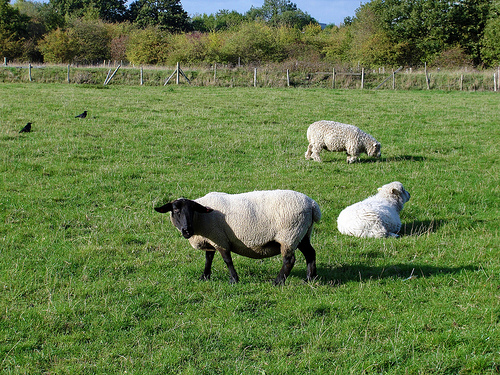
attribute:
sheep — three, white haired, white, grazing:
[171, 102, 421, 271]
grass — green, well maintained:
[4, 81, 488, 260]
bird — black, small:
[9, 119, 32, 147]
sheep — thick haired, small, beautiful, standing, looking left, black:
[184, 194, 322, 268]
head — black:
[164, 194, 199, 242]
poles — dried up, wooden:
[170, 59, 188, 84]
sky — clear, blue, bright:
[299, 1, 359, 20]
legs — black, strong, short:
[193, 258, 243, 290]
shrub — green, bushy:
[226, 24, 294, 64]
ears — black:
[154, 199, 218, 212]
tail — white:
[312, 202, 323, 222]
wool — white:
[254, 223, 279, 233]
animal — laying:
[351, 169, 420, 247]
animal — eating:
[299, 118, 384, 165]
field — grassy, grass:
[41, 59, 491, 271]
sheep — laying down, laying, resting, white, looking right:
[344, 190, 428, 243]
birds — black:
[4, 104, 106, 150]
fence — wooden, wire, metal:
[34, 63, 478, 90]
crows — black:
[17, 106, 99, 144]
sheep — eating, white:
[305, 121, 370, 145]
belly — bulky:
[229, 234, 280, 263]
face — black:
[170, 194, 198, 232]